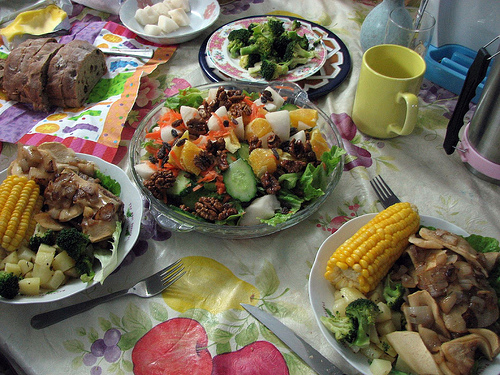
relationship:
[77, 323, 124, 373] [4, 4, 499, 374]
grapes on cloth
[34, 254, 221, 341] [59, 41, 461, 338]
fork on table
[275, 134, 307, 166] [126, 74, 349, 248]
brocolli on plate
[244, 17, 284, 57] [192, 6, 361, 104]
brocolli on plate